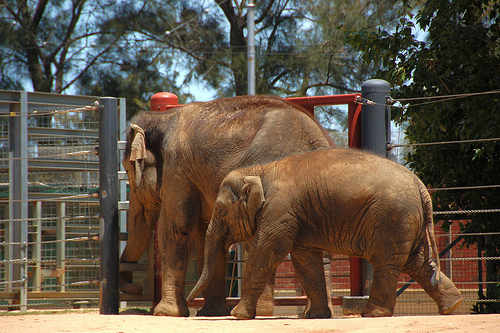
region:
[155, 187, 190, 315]
grey leg of elephant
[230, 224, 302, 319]
grey leg of elephant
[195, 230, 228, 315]
grey leg of elephant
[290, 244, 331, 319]
grey leg of elephant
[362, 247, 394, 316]
grey leg of elephant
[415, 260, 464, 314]
grey leg of elephant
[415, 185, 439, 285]
grey tail of elephant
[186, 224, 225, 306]
grey trunk of elephant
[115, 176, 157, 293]
grey trunk of elephant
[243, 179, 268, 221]
grey ear of elephant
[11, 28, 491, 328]
Elephants in an enclosure.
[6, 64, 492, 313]
Fence surrounding enclosure.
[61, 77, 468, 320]
Small elephant walking behind big one.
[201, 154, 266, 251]
Head of small elephant.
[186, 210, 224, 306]
Trunk of small elephant.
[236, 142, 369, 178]
Hair on back of small elephant.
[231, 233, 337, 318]
Front legs of small elephant.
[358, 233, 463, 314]
Back legs of small elephant.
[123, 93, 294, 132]
Hair on back of large elephant.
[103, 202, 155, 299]
Trunk of large elephant.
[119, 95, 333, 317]
Larger elephant in a pen.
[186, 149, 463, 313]
Smaller elephant in a pen.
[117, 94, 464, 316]
Two elephants in a pen.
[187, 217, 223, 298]
Trunk on the smaller elephant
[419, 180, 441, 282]
Tail on the smaller elephant.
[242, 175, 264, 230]
Ear on the smaller elephant.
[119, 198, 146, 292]
Trunk on the larger elephant.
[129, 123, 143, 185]
Ear on the larger elephant.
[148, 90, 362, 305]
Red gate behind elephants.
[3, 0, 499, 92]
Trees behind elephant enclosure.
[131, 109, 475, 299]
a mother and baby elephant walking together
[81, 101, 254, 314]
a full grown adult elephant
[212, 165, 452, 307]
a small little baby elephant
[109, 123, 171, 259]
the head of an adult elephant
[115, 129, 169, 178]
the ear of an adult elephant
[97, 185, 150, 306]
the trunk of an adult elephant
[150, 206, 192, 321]
the left leg of an adult elephant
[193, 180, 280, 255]
the head of a baby elephant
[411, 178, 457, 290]
the tail of an elephant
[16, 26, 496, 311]
The elephants are in a zoo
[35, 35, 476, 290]
The elephants are male and female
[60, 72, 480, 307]
The elephants are walking around slowly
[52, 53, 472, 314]
The elephants are looking for food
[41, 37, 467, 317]
The elephants are wanting to be fed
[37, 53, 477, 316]
The elephants are enjoying the sunshine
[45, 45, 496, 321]
The elephants are trying to play nicely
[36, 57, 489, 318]
The elephants are enjoying the day